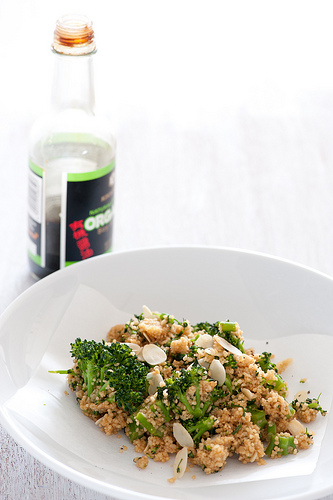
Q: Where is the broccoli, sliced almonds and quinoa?
A: Inside a white bowl.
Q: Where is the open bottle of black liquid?
A: Behind the white bowl.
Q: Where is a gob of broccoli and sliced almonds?
A: In a bowl.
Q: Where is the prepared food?
A: Center of white bowl.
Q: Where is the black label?
A: On the clear glass bottle.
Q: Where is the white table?
A: Under the white bowl.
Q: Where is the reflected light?
A: On a white bowl.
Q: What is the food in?
A: White bowl.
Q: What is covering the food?
A: Almond slices.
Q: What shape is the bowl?
A: Round.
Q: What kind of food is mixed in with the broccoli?
A: Tan colored rice like food.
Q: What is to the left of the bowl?
A: Bottle.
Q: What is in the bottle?
A: Brown beverage.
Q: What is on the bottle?
A: Label.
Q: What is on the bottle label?
A: White writing.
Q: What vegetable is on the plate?
A: Broccoli.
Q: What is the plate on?
A: A table.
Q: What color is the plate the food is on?
A: White.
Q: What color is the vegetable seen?
A: Green.